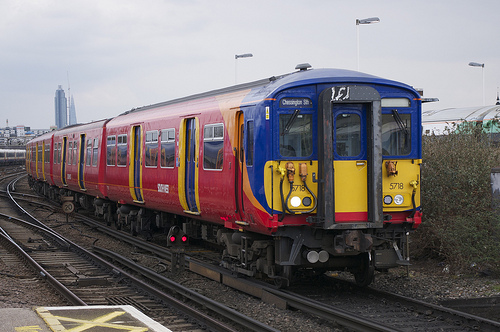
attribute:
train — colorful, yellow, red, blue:
[25, 63, 422, 284]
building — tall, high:
[55, 84, 67, 128]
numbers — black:
[390, 182, 401, 189]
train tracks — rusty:
[1, 171, 499, 331]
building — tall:
[70, 96, 78, 124]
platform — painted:
[34, 303, 174, 329]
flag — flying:
[468, 62, 486, 69]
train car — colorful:
[52, 117, 109, 197]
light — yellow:
[288, 196, 299, 207]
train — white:
[1, 149, 26, 167]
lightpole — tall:
[67, 77, 73, 97]